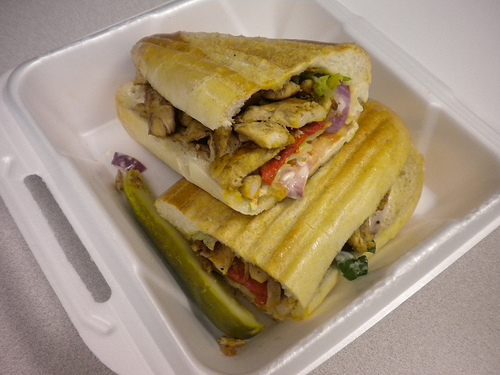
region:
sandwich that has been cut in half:
[92, 21, 436, 313]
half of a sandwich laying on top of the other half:
[93, 26, 438, 309]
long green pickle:
[115, 171, 264, 346]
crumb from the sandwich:
[213, 333, 246, 355]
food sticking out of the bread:
[235, 78, 347, 193]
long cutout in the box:
[21, 168, 114, 314]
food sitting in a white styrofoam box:
[1, 8, 492, 372]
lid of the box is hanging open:
[356, 6, 498, 130]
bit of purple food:
[108, 148, 140, 173]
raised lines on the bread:
[269, 123, 396, 265]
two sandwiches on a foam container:
[92, 20, 442, 340]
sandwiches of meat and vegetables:
[97, 15, 433, 352]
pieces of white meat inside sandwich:
[235, 90, 330, 150]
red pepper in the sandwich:
[257, 120, 330, 185]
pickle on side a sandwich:
[107, 150, 272, 360]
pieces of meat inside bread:
[112, 60, 347, 202]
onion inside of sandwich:
[321, 77, 358, 142]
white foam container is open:
[0, 0, 499, 374]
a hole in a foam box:
[7, 158, 127, 320]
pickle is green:
[111, 154, 272, 357]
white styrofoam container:
[5, 4, 485, 371]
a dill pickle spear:
[109, 160, 251, 362]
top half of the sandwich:
[107, 26, 387, 220]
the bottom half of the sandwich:
[150, 104, 478, 318]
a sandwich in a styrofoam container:
[39, 8, 498, 355]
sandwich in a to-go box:
[13, 4, 485, 352]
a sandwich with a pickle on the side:
[25, 20, 456, 342]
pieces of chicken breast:
[245, 93, 328, 142]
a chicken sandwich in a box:
[18, 11, 458, 350]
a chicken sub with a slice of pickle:
[32, 16, 482, 350]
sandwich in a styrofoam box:
[25, 26, 454, 319]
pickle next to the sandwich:
[105, 160, 260, 352]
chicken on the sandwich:
[247, 104, 323, 142]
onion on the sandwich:
[283, 166, 318, 201]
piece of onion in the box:
[109, 141, 143, 184]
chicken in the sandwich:
[142, 89, 184, 147]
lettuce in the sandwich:
[307, 57, 350, 99]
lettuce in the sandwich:
[341, 239, 379, 301]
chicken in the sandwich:
[201, 233, 235, 279]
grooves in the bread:
[295, 140, 350, 275]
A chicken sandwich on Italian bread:
[122, 34, 372, 206]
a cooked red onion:
[277, 160, 314, 205]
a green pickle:
[114, 165, 167, 267]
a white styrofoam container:
[42, 117, 117, 357]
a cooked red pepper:
[230, 258, 270, 320]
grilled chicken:
[259, 105, 328, 130]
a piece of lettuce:
[314, 69, 349, 104]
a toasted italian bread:
[287, 225, 329, 297]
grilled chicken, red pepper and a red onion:
[253, 96, 323, 198]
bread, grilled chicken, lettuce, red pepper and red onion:
[302, 42, 380, 144]